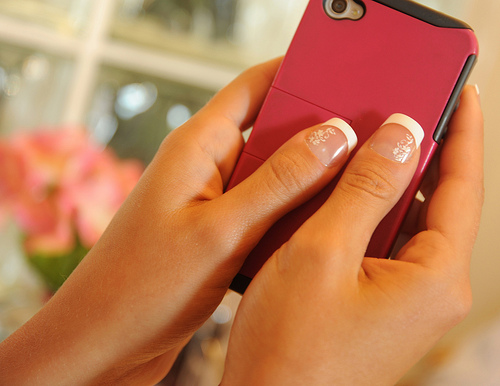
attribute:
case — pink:
[210, 6, 487, 283]